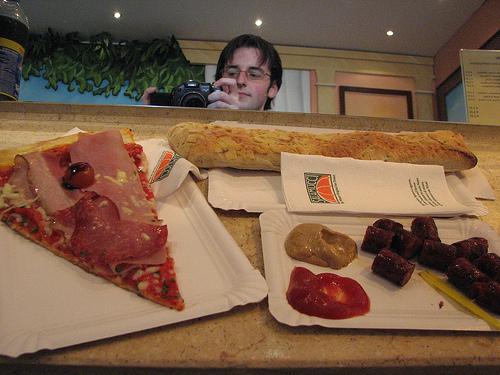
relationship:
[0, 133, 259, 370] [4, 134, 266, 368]
pizza on tray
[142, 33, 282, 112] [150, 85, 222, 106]
man holding camera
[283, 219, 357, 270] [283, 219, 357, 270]
condiments dipping condiments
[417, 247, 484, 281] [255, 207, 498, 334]
sausage on plate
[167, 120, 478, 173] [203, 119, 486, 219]
baguette on plate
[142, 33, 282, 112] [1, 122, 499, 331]
man photographed food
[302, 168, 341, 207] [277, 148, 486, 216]
logo on napkin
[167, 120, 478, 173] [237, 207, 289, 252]
baguette on plate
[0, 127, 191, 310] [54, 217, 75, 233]
pizza with cheese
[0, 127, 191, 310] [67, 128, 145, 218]
pizza slices of meat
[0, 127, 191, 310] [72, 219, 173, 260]
pizza slices of meat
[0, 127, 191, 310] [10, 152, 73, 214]
pizza slices of meat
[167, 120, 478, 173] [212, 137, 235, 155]
baguette with cheese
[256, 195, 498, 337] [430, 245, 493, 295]
plate with sausage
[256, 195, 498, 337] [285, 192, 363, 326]
plate with condiments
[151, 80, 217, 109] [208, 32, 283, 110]
camera used by man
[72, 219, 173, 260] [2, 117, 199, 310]
meat on pizza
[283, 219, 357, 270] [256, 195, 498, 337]
condiments on plate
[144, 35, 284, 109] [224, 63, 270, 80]
glasses of man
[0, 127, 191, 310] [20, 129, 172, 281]
pizza covered in toppings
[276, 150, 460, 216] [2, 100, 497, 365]
napkin on table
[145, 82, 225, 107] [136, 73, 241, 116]
camera in hand